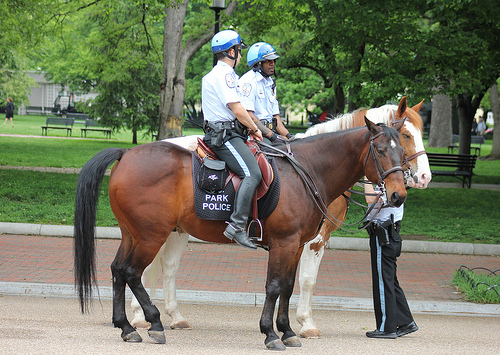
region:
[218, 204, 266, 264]
A police man's shoe.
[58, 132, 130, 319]
A horses black tail.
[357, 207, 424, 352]
A police man's pants.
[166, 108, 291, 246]
A brown horse saddle.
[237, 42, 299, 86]
A police man's helmet.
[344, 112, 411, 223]
A horses head.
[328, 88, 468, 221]
Two brown horses heads.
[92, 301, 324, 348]
4 black horse hooves.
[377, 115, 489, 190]
The black bench in the park.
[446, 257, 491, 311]
The green grass and weeds.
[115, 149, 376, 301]
A brown horse.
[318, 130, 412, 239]
The harness and reins on a brown horse.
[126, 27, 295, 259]
A police officer is riding a horse.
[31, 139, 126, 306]
A black long tail on a brown horse.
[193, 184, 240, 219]
A saddle bag that states Park Police.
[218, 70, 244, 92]
A police insignia on the sleeve of a shirt.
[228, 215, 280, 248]
A silver stirrup.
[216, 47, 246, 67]
A strap holding a police helmet on.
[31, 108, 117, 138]
Two park benches.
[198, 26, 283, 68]
Two blue police helmets.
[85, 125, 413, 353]
The horse is dark brown with black legs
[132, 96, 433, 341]
The horse is brown with white legs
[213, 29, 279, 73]
The policemen are wearing blue and white helmets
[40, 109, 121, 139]
The park benches are black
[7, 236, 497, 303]
The street is made of red brick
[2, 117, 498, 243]
The grass is green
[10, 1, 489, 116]
The trees are full and green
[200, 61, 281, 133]
The policemen's shirts are white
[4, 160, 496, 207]
The sidewalk is gray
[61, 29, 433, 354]
The policemen are riding on horses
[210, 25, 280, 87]
Blue helmets for protection.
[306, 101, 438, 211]
Horses are brown and white.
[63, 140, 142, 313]
Completely brown horses' tail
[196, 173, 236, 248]
Sign says "Park Police"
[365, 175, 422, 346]
Police Officer hidden by horses.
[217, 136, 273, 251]
Officer has leg out of stirrups.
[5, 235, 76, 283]
Roadway made of bricks.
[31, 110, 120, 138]
Two park bench's in background.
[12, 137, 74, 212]
Park's grass is green.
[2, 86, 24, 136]
Person walking in background.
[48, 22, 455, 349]
Policemen sitting on horses.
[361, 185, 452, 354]
Bottom half of policeman standing next to horses.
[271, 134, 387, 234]
A horse's black reins.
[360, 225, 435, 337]
Policeman wearing black pants with blue stripe.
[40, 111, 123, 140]
Green benches sitting in park.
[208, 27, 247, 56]
Policeman wearing white and blue helmet.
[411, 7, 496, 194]
Tree growing in park.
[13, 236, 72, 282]
A red brick sidewalk.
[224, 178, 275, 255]
Policeman wearing knee boots.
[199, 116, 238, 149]
Policeman wearing fire arm.